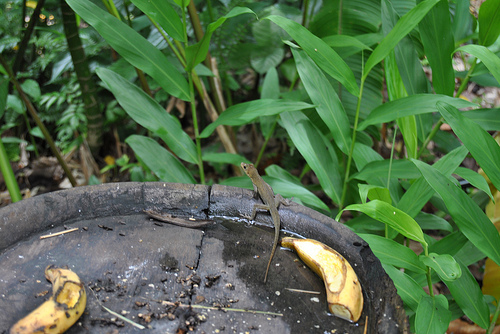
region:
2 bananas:
[22, 270, 347, 332]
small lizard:
[186, 147, 308, 233]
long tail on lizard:
[270, 203, 285, 284]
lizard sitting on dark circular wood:
[35, 140, 352, 263]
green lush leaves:
[91, 21, 487, 213]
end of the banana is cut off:
[318, 282, 370, 332]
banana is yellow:
[247, 231, 372, 318]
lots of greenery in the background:
[21, 10, 493, 194]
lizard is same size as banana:
[228, 155, 292, 281]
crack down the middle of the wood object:
[178, 181, 224, 332]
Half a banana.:
[281, 230, 365, 322]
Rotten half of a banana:
[3, 262, 92, 332]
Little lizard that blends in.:
[234, 159, 286, 287]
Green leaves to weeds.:
[404, 149, 489, 299]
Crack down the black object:
[183, 174, 216, 332]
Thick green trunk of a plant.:
[51, 0, 111, 139]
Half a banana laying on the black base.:
[287, 234, 366, 321]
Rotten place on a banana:
[50, 279, 87, 316]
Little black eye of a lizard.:
[239, 163, 250, 170]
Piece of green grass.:
[157, 297, 286, 322]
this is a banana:
[278, 233, 368, 317]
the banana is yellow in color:
[273, 232, 365, 320]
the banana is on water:
[276, 233, 368, 323]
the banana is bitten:
[48, 277, 82, 308]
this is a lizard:
[240, 161, 279, 277]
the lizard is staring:
[241, 161, 284, 273]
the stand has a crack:
[147, 184, 228, 330]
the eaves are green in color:
[354, 56, 474, 241]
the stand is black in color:
[105, 231, 156, 329]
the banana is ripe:
[285, 226, 363, 327]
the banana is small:
[280, 233, 357, 315]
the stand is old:
[102, 186, 232, 331]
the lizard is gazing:
[229, 161, 265, 188]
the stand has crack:
[160, 200, 230, 325]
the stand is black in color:
[127, 191, 233, 318]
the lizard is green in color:
[240, 162, 280, 266]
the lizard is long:
[235, 162, 280, 273]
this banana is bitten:
[45, 280, 81, 307]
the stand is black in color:
[90, 240, 237, 326]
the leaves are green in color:
[138, 18, 426, 143]